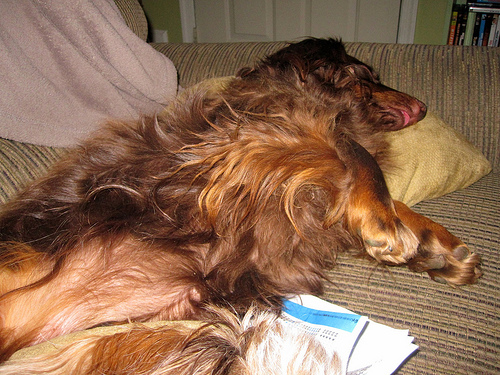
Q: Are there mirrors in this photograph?
A: No, there are no mirrors.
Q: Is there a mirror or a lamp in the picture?
A: No, there are no mirrors or lamps.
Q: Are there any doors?
A: Yes, there is a door.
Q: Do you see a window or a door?
A: Yes, there is a door.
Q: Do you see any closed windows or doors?
A: Yes, there is a closed door.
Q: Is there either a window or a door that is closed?
A: Yes, the door is closed.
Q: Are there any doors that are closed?
A: Yes, there is a closed door.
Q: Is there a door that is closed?
A: Yes, there is a door that is closed.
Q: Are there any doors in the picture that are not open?
A: Yes, there is an closed door.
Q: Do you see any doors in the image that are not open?
A: Yes, there is an closed door.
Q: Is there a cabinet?
A: No, there are no cabinets.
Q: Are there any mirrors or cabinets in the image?
A: No, there are no cabinets or mirrors.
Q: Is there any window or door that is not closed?
A: No, there is a door but it is closed.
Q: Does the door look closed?
A: Yes, the door is closed.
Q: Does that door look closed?
A: Yes, the door is closed.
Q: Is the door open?
A: No, the door is closed.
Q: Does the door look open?
A: No, the door is closed.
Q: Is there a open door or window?
A: No, there is a door but it is closed.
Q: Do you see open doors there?
A: No, there is a door but it is closed.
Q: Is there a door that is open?
A: No, there is a door but it is closed.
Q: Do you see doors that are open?
A: No, there is a door but it is closed.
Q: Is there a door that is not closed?
A: No, there is a door but it is closed.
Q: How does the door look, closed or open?
A: The door is closed.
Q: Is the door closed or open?
A: The door is closed.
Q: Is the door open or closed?
A: The door is closed.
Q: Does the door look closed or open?
A: The door is closed.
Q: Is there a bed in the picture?
A: No, there are no beds.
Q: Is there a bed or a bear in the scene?
A: No, there are no beds or bears.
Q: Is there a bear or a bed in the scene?
A: No, there are no beds or bears.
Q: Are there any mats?
A: No, there are no mats.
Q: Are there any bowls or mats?
A: No, there are no mats or bowls.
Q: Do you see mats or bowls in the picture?
A: No, there are no mats or bowls.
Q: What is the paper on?
A: The paper is on the couch.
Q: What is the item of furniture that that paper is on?
A: The piece of furniture is a couch.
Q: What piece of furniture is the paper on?
A: The paper is on the couch.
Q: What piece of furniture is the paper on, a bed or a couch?
A: The paper is on a couch.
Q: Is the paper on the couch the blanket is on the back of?
A: Yes, the paper is on the couch.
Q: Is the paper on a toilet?
A: No, the paper is on the couch.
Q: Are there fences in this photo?
A: No, there are no fences.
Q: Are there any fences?
A: No, there are no fences.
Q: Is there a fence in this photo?
A: No, there are no fences.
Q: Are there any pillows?
A: Yes, there is a pillow.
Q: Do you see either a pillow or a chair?
A: Yes, there is a pillow.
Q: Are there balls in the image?
A: No, there are no balls.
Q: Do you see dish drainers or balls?
A: No, there are no balls or dish drainers.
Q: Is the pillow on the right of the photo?
A: Yes, the pillow is on the right of the image.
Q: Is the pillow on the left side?
A: No, the pillow is on the right of the image.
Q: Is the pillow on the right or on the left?
A: The pillow is on the right of the image.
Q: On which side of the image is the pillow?
A: The pillow is on the right of the image.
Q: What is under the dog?
A: The pillow is under the dog.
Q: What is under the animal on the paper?
A: The pillow is under the dog.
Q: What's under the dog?
A: The pillow is under the dog.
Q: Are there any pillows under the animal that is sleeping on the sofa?
A: Yes, there is a pillow under the dog.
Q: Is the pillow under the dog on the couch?
A: Yes, the pillow is under the dog.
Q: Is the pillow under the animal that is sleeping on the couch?
A: Yes, the pillow is under the dog.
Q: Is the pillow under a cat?
A: No, the pillow is under the dog.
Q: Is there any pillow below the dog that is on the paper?
A: Yes, there is a pillow below the dog.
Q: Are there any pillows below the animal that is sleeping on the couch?
A: Yes, there is a pillow below the dog.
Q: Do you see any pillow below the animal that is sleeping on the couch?
A: Yes, there is a pillow below the dog.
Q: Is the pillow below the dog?
A: Yes, the pillow is below the dog.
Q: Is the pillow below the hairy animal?
A: Yes, the pillow is below the dog.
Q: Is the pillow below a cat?
A: No, the pillow is below the dog.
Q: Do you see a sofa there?
A: Yes, there is a sofa.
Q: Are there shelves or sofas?
A: Yes, there is a sofa.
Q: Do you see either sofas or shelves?
A: Yes, there is a sofa.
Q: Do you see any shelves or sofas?
A: Yes, there is a sofa.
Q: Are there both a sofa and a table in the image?
A: No, there is a sofa but no tables.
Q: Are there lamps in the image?
A: No, there are no lamps.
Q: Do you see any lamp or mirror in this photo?
A: No, there are no lamps or mirrors.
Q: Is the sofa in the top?
A: Yes, the sofa is in the top of the image.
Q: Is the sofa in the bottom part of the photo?
A: No, the sofa is in the top of the image.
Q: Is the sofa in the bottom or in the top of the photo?
A: The sofa is in the top of the image.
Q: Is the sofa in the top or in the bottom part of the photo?
A: The sofa is in the top of the image.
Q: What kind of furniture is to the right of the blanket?
A: The piece of furniture is a sofa.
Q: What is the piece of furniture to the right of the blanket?
A: The piece of furniture is a sofa.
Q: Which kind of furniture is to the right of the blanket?
A: The piece of furniture is a sofa.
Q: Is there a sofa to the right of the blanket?
A: Yes, there is a sofa to the right of the blanket.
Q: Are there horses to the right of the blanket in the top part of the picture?
A: No, there is a sofa to the right of the blanket.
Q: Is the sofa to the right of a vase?
A: No, the sofa is to the right of a blanket.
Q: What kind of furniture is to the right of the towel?
A: The piece of furniture is a sofa.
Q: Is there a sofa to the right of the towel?
A: Yes, there is a sofa to the right of the towel.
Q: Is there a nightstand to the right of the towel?
A: No, there is a sofa to the right of the towel.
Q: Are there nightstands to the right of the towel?
A: No, there is a sofa to the right of the towel.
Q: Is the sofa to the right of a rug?
A: No, the sofa is to the right of a towel.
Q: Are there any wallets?
A: No, there are no wallets.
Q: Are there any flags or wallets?
A: No, there are no wallets or flags.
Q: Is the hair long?
A: Yes, the hair is long.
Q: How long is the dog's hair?
A: The hair is long.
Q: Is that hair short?
A: No, the hair is long.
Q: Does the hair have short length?
A: No, the hair is long.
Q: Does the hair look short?
A: No, the hair is long.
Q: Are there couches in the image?
A: Yes, there is a couch.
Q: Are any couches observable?
A: Yes, there is a couch.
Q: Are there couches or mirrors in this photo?
A: Yes, there is a couch.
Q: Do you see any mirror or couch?
A: Yes, there is a couch.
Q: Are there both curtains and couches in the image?
A: No, there is a couch but no curtains.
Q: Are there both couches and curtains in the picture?
A: No, there is a couch but no curtains.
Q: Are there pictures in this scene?
A: No, there are no pictures.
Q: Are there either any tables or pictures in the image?
A: No, there are no pictures or tables.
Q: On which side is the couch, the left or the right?
A: The couch is on the right of the image.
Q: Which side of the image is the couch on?
A: The couch is on the right of the image.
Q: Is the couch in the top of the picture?
A: Yes, the couch is in the top of the image.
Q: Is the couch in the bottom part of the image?
A: No, the couch is in the top of the image.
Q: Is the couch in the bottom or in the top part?
A: The couch is in the top of the image.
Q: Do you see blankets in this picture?
A: Yes, there is a blanket.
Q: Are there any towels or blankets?
A: Yes, there is a blanket.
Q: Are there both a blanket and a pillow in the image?
A: Yes, there are both a blanket and a pillow.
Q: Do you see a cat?
A: No, there are no cats.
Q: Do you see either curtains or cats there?
A: No, there are no cats or curtains.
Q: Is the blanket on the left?
A: Yes, the blanket is on the left of the image.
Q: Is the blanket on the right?
A: No, the blanket is on the left of the image.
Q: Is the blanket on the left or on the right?
A: The blanket is on the left of the image.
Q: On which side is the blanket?
A: The blanket is on the left of the image.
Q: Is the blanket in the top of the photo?
A: Yes, the blanket is in the top of the image.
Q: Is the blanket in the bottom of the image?
A: No, the blanket is in the top of the image.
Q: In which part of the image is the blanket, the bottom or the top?
A: The blanket is in the top of the image.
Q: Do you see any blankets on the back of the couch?
A: Yes, there is a blanket on the back of the couch.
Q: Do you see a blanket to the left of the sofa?
A: Yes, there is a blanket to the left of the sofa.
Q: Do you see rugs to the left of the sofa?
A: No, there is a blanket to the left of the sofa.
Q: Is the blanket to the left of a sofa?
A: Yes, the blanket is to the left of a sofa.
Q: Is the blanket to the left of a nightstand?
A: No, the blanket is to the left of a sofa.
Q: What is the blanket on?
A: The blanket is on the couch.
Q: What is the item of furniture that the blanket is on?
A: The piece of furniture is a couch.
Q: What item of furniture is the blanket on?
A: The blanket is on the couch.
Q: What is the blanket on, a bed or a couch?
A: The blanket is on a couch.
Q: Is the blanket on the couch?
A: Yes, the blanket is on the couch.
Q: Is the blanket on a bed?
A: No, the blanket is on the couch.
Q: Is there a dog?
A: Yes, there is a dog.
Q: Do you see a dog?
A: Yes, there is a dog.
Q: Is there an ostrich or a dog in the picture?
A: Yes, there is a dog.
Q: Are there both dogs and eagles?
A: No, there is a dog but no eagles.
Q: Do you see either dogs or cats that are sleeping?
A: Yes, the dog is sleeping.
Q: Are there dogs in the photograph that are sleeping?
A: Yes, there is a dog that is sleeping.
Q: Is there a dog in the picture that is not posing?
A: Yes, there is a dog that is sleeping.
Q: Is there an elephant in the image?
A: No, there are no elephants.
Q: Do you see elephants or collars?
A: No, there are no elephants or collars.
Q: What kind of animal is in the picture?
A: The animal is a dog.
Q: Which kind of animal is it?
A: The animal is a dog.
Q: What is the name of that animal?
A: This is a dog.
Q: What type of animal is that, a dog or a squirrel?
A: This is a dog.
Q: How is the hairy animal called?
A: The animal is a dog.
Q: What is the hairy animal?
A: The animal is a dog.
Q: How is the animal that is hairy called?
A: The animal is a dog.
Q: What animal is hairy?
A: The animal is a dog.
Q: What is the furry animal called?
A: The animal is a dog.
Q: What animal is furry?
A: The animal is a dog.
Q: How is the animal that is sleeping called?
A: The animal is a dog.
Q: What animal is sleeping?
A: The animal is a dog.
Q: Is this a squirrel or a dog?
A: This is a dog.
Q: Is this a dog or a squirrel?
A: This is a dog.